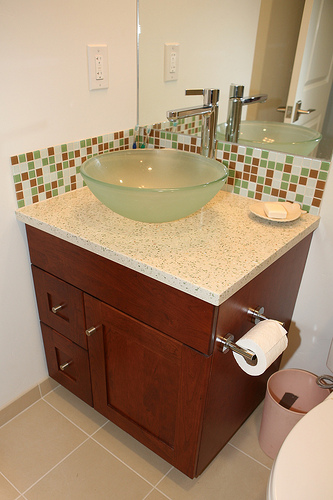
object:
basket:
[257, 362, 331, 465]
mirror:
[137, 0, 332, 163]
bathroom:
[0, 5, 333, 500]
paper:
[232, 318, 290, 380]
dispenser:
[217, 307, 284, 360]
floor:
[0, 381, 277, 499]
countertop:
[15, 149, 320, 306]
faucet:
[166, 86, 221, 126]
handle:
[185, 87, 223, 105]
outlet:
[86, 43, 110, 91]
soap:
[264, 202, 288, 219]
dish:
[249, 200, 302, 222]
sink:
[77, 148, 230, 225]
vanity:
[16, 164, 319, 480]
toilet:
[263, 385, 331, 499]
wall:
[3, 3, 134, 204]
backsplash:
[8, 125, 329, 217]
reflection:
[278, 3, 331, 157]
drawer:
[33, 266, 88, 351]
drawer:
[40, 322, 93, 408]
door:
[84, 294, 206, 479]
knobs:
[85, 324, 96, 338]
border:
[0, 372, 64, 411]